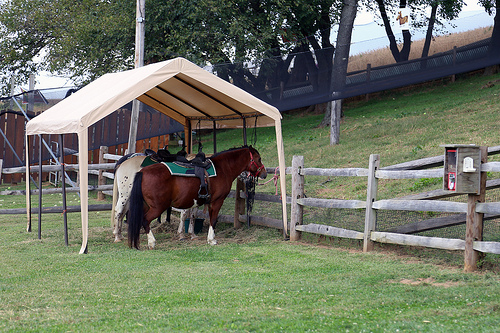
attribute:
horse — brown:
[142, 152, 249, 231]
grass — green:
[157, 246, 276, 321]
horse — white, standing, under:
[109, 155, 199, 249]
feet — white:
[139, 221, 226, 254]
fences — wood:
[226, 117, 468, 328]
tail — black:
[123, 172, 151, 258]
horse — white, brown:
[111, 152, 152, 244]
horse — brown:
[119, 146, 266, 248]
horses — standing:
[88, 137, 279, 259]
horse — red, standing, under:
[126, 144, 271, 246]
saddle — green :
[175, 146, 217, 206]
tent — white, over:
[24, 55, 291, 253]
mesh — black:
[1, 10, 498, 169]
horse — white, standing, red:
[130, 126, 263, 246]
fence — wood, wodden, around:
[0, 140, 500, 271]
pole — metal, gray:
[58, 137, 69, 244]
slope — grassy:
[282, 79, 480, 194]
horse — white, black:
[101, 129, 297, 260]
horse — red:
[152, 145, 267, 246]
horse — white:
[112, 137, 150, 239]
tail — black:
[122, 169, 148, 251]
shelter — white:
[34, 77, 236, 235]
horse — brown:
[129, 152, 278, 250]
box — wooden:
[430, 139, 487, 216]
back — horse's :
[149, 149, 233, 183]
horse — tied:
[126, 143, 263, 252]